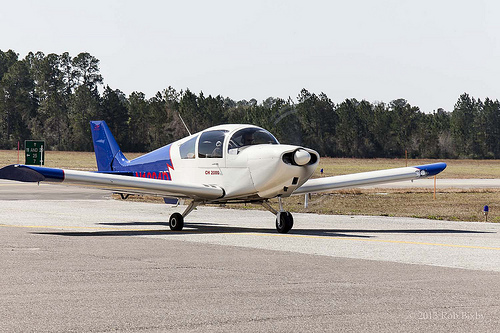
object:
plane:
[0, 114, 446, 233]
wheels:
[272, 209, 294, 232]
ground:
[0, 178, 499, 332]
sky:
[0, 0, 498, 115]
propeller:
[290, 149, 312, 165]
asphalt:
[0, 179, 499, 332]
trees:
[0, 50, 499, 161]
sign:
[25, 139, 46, 166]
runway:
[0, 198, 499, 273]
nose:
[275, 144, 321, 175]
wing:
[0, 162, 225, 199]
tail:
[88, 119, 126, 159]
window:
[197, 130, 228, 158]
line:
[226, 229, 500, 251]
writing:
[204, 170, 221, 177]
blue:
[97, 140, 162, 170]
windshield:
[225, 127, 281, 153]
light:
[479, 206, 489, 219]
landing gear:
[183, 192, 279, 219]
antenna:
[173, 114, 193, 138]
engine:
[160, 196, 181, 205]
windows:
[178, 136, 196, 161]